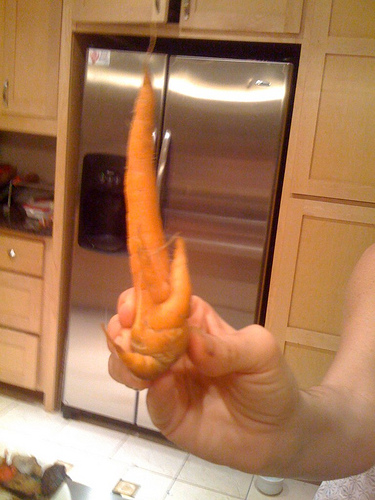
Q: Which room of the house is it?
A: It is a kitchen.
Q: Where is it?
A: This is at the kitchen.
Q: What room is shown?
A: It is a kitchen.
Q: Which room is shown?
A: It is a kitchen.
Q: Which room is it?
A: It is a kitchen.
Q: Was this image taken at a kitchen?
A: Yes, it was taken in a kitchen.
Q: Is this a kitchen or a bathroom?
A: It is a kitchen.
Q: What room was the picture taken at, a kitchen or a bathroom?
A: It was taken at a kitchen.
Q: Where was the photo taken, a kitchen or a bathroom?
A: It was taken at a kitchen.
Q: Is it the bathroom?
A: No, it is the kitchen.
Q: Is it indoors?
A: Yes, it is indoors.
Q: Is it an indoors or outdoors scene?
A: It is indoors.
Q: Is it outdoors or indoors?
A: It is indoors.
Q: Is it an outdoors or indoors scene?
A: It is indoors.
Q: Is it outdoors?
A: No, it is indoors.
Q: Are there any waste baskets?
A: No, there are no waste baskets.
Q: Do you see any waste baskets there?
A: No, there are no waste baskets.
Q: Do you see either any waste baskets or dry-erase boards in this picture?
A: No, there are no waste baskets or dry-erase boards.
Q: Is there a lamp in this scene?
A: No, there are no lamps.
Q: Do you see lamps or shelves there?
A: No, there are no lamps or shelves.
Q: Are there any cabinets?
A: Yes, there is a cabinet.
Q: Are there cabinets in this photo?
A: Yes, there is a cabinet.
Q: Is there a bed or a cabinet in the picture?
A: Yes, there is a cabinet.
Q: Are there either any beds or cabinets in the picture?
A: Yes, there is a cabinet.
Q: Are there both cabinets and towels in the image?
A: No, there is a cabinet but no towels.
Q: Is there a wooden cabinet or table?
A: Yes, there is a wood cabinet.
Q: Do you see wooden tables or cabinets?
A: Yes, there is a wood cabinet.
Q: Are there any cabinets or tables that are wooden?
A: Yes, the cabinet is wooden.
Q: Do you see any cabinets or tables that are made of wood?
A: Yes, the cabinet is made of wood.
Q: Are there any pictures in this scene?
A: No, there are no pictures.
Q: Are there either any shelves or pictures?
A: No, there are no pictures or shelves.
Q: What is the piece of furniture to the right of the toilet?
A: The piece of furniture is a cabinet.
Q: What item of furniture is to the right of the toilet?
A: The piece of furniture is a cabinet.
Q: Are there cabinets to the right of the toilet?
A: Yes, there is a cabinet to the right of the toilet.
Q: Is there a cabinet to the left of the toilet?
A: No, the cabinet is to the right of the toilet.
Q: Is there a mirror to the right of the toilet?
A: No, there is a cabinet to the right of the toilet.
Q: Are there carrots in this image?
A: Yes, there are carrots.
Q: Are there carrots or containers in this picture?
A: Yes, there are carrots.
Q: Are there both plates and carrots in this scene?
A: No, there are carrots but no plates.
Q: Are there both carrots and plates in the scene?
A: No, there are carrots but no plates.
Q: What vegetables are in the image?
A: The vegetables are carrots.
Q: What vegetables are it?
A: The vegetables are carrots.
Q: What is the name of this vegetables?
A: These are carrots.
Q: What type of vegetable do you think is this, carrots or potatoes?
A: These are carrots.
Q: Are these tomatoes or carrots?
A: These are carrots.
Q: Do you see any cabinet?
A: Yes, there is a cabinet.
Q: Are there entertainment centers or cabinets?
A: Yes, there is a cabinet.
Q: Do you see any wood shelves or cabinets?
A: Yes, there is a wood cabinet.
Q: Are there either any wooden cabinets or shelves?
A: Yes, there is a wood cabinet.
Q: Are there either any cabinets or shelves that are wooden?
A: Yes, the cabinet is wooden.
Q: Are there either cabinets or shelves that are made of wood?
A: Yes, the cabinet is made of wood.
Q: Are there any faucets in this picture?
A: No, there are no faucets.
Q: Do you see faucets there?
A: No, there are no faucets.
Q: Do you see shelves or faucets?
A: No, there are no faucets or shelves.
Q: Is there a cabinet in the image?
A: Yes, there is a cabinet.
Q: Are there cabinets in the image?
A: Yes, there is a cabinet.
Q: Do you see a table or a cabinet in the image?
A: Yes, there is a cabinet.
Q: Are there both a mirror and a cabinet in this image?
A: No, there is a cabinet but no mirrors.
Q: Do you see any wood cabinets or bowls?
A: Yes, there is a wood cabinet.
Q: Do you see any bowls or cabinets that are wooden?
A: Yes, the cabinet is wooden.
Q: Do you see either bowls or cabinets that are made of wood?
A: Yes, the cabinet is made of wood.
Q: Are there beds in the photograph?
A: No, there are no beds.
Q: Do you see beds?
A: No, there are no beds.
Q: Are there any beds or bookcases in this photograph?
A: No, there are no beds or bookcases.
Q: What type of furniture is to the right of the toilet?
A: The piece of furniture is a cabinet.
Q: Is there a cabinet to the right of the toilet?
A: Yes, there is a cabinet to the right of the toilet.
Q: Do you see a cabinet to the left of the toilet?
A: No, the cabinet is to the right of the toilet.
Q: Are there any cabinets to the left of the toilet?
A: No, the cabinet is to the right of the toilet.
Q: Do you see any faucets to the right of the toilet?
A: No, there is a cabinet to the right of the toilet.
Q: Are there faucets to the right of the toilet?
A: No, there is a cabinet to the right of the toilet.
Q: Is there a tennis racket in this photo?
A: No, there are no rackets.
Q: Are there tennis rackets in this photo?
A: No, there are no tennis rackets.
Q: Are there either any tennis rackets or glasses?
A: No, there are no tennis rackets or glasses.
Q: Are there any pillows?
A: No, there are no pillows.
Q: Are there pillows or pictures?
A: No, there are no pillows or pictures.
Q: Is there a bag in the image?
A: No, there are no bags.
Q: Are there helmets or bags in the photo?
A: No, there are no bags or helmets.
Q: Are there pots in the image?
A: No, there are no pots.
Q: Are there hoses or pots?
A: No, there are no pots or hoses.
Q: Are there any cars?
A: No, there are no cars.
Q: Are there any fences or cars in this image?
A: No, there are no cars or fences.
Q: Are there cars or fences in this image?
A: No, there are no cars or fences.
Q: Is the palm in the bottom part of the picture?
A: Yes, the palm is in the bottom of the image.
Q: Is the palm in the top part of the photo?
A: No, the palm is in the bottom of the image.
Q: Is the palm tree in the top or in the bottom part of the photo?
A: The palm tree is in the bottom of the image.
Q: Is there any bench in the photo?
A: No, there are no benches.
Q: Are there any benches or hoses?
A: No, there are no benches or hoses.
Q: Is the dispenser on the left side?
A: Yes, the dispenser is on the left of the image.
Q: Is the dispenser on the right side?
A: No, the dispenser is on the left of the image.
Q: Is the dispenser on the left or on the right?
A: The dispenser is on the left of the image.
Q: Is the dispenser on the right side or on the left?
A: The dispenser is on the left of the image.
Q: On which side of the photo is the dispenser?
A: The dispenser is on the left of the image.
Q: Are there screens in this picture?
A: No, there are no screens.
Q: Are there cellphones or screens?
A: No, there are no screens or cellphones.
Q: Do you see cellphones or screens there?
A: No, there are no screens or cellphones.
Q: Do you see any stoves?
A: No, there are no stoves.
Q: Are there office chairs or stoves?
A: No, there are no stoves or office chairs.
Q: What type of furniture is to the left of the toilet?
A: The pieces of furniture are cabinets.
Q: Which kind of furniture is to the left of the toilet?
A: The pieces of furniture are cabinets.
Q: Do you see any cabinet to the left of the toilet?
A: Yes, there are cabinets to the left of the toilet.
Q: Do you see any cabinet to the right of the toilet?
A: No, the cabinets are to the left of the toilet.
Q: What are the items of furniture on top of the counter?
A: The pieces of furniture are cabinets.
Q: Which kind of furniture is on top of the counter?
A: The pieces of furniture are cabinets.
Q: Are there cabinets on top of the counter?
A: Yes, there are cabinets on top of the counter.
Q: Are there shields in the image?
A: No, there are no shields.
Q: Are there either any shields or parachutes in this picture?
A: No, there are no shields or parachutes.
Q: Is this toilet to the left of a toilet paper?
A: No, the toilet is to the left of a cabinet.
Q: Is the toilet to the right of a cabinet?
A: No, the toilet is to the left of a cabinet.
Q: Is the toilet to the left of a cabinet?
A: Yes, the toilet is to the left of a cabinet.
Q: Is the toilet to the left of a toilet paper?
A: No, the toilet is to the left of a cabinet.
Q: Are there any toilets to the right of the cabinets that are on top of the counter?
A: Yes, there is a toilet to the right of the cabinets.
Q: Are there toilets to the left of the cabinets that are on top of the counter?
A: No, the toilet is to the right of the cabinets.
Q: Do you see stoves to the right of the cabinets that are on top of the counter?
A: No, there is a toilet to the right of the cabinets.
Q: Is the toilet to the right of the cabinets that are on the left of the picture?
A: Yes, the toilet is to the right of the cabinets.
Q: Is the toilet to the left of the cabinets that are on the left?
A: No, the toilet is to the right of the cabinets.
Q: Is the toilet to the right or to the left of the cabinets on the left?
A: The toilet is to the right of the cabinets.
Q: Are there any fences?
A: No, there are no fences.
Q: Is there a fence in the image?
A: No, there are no fences.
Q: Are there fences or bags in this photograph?
A: No, there are no fences or bags.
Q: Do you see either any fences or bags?
A: No, there are no fences or bags.